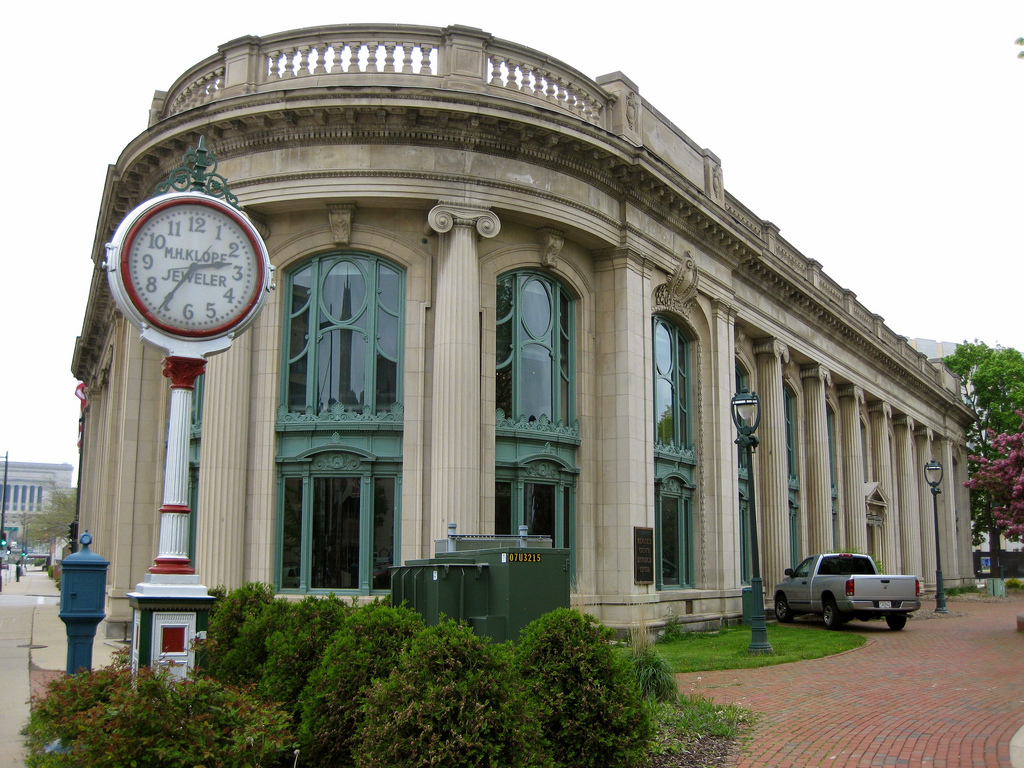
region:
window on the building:
[272, 285, 399, 406]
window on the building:
[506, 471, 571, 544]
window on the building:
[472, 287, 575, 433]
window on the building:
[648, 325, 691, 456]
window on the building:
[661, 478, 704, 578]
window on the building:
[728, 508, 757, 585]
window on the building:
[775, 411, 810, 479]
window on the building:
[788, 509, 817, 554]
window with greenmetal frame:
[281, 249, 405, 427]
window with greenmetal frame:
[495, 265, 581, 443]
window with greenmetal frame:
[495, 429, 581, 550]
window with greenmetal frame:
[654, 309, 697, 462]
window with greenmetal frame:
[654, 455, 694, 588]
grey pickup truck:
[774, 553, 921, 631]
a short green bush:
[514, 605, 651, 764]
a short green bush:
[344, 617, 548, 767]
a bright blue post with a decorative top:
[46, 521, 116, 699]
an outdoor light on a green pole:
[723, 379, 784, 668]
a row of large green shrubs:
[201, 563, 541, 766]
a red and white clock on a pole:
[103, 177, 288, 394]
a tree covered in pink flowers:
[961, 392, 1022, 530]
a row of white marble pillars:
[6, 483, 52, 522]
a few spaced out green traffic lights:
[0, 534, 35, 564]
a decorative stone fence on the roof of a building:
[142, 31, 629, 139]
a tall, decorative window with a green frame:
[490, 263, 590, 461]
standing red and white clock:
[91, 186, 282, 686]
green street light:
[723, 382, 782, 658]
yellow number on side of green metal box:
[502, 547, 550, 568]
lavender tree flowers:
[955, 396, 1022, 546]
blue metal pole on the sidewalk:
[43, 527, 110, 756]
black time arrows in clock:
[147, 246, 239, 316]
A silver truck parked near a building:
[770, 542, 927, 641]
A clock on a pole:
[119, 191, 279, 351]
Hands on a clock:
[156, 243, 230, 307]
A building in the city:
[65, 28, 976, 642]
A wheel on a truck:
[814, 589, 852, 631]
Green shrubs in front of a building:
[19, 583, 656, 764]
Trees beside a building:
[938, 338, 1021, 580]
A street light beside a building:
[921, 450, 961, 624]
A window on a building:
[280, 238, 407, 416]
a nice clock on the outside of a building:
[106, 189, 272, 686]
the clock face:
[127, 202, 261, 330]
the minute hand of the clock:
[155, 260, 203, 318]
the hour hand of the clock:
[171, 257, 235, 276]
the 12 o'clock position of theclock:
[187, 192, 208, 243]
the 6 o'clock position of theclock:
[177, 294, 196, 324]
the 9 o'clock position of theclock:
[131, 247, 160, 271]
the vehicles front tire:
[769, 581, 798, 626]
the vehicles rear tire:
[820, 598, 841, 633]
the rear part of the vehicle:
[832, 566, 927, 617]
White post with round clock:
[101, 121, 275, 688]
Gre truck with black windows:
[769, 551, 919, 629]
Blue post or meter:
[58, 531, 109, 684]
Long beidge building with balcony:
[70, 22, 978, 637]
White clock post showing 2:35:
[104, 124, 276, 688]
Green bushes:
[0, 584, 653, 762]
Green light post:
[730, 389, 769, 652]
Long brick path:
[665, 594, 1021, 766]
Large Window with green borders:
[272, 246, 406, 595]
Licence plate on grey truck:
[769, 554, 918, 627]